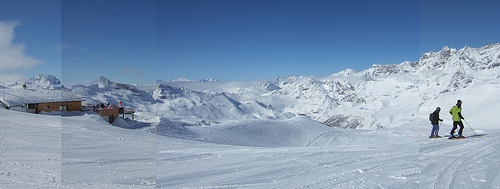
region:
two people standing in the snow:
[420, 68, 482, 140]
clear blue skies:
[0, 0, 499, 90]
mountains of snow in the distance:
[114, 63, 368, 149]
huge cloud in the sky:
[3, 21, 57, 78]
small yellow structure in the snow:
[8, 81, 132, 127]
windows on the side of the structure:
[18, 103, 86, 115]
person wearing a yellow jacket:
[448, 91, 478, 142]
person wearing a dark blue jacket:
[414, 98, 447, 143]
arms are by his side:
[418, 102, 445, 144]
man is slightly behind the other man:
[414, 101, 451, 146]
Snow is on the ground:
[33, 22, 488, 173]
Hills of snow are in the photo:
[25, 53, 495, 158]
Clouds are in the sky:
[0, 11, 99, 96]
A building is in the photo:
[31, 61, 271, 171]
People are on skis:
[256, 42, 481, 169]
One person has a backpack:
[385, 69, 468, 152]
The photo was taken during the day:
[27, 14, 419, 175]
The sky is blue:
[53, 12, 478, 186]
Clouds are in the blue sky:
[0, 7, 434, 157]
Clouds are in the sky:
[3, 5, 464, 170]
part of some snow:
[331, 109, 396, 166]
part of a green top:
[448, 103, 458, 121]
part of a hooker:
[471, 114, 477, 144]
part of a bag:
[426, 105, 436, 126]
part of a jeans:
[428, 124, 440, 139]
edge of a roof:
[53, 92, 72, 103]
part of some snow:
[151, 110, 188, 148]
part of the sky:
[201, 20, 271, 90]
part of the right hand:
[432, 114, 447, 123]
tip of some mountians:
[414, 18, 479, 74]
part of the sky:
[251, 5, 308, 59]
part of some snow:
[283, 155, 318, 185]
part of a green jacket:
[448, 110, 459, 122]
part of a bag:
[423, 110, 434, 128]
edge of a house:
[52, 93, 79, 105]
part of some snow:
[278, 83, 320, 135]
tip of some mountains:
[407, 31, 461, 76]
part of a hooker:
[460, 116, 473, 136]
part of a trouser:
[433, 125, 440, 130]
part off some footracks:
[431, 154, 467, 180]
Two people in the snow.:
[329, 60, 485, 167]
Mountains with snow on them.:
[305, 20, 499, 104]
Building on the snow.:
[30, 67, 149, 137]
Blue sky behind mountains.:
[202, 5, 405, 116]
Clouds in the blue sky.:
[10, 18, 95, 87]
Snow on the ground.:
[115, 120, 324, 183]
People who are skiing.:
[383, 91, 495, 156]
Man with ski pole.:
[460, 105, 477, 148]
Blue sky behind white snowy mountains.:
[237, 31, 471, 127]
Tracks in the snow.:
[250, 97, 465, 185]